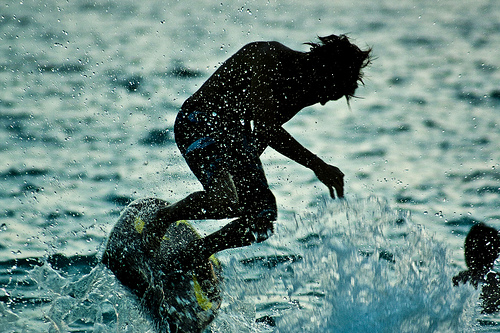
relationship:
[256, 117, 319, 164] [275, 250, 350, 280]
arm sticking out toward water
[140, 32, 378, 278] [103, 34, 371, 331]
guy in silhouette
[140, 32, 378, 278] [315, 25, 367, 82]
guy has hair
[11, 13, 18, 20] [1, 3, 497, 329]
water on lens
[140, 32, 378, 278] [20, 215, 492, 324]
guy standing on waves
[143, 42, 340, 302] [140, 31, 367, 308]
mist on surfer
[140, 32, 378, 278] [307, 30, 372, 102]
guy has hair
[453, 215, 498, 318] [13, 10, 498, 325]
object in picture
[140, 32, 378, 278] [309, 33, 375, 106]
guy with hair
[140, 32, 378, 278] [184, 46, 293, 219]
guy wearing a wet suit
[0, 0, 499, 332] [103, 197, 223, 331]
water spraying over surfboard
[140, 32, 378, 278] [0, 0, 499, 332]
guy in water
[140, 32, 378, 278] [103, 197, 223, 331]
guy on surfboard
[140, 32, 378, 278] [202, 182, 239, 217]
guy has knee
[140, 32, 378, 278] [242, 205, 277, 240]
guy has knee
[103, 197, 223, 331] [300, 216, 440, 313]
surfboard splashing water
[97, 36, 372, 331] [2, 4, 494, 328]
guy riding water